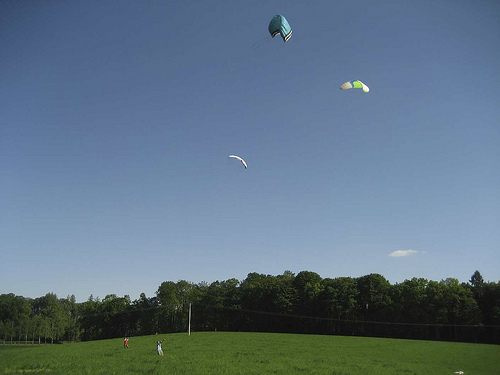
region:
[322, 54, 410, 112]
the kite is yellow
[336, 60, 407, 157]
the kite is yellow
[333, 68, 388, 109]
the kite is yellow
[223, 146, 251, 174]
A white kite im the air.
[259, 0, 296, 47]
A blue kite.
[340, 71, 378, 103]
A white and green kite.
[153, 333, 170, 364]
A boy holding a kite.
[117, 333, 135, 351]
A boy holding another kite.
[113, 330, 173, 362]
Two boys in a field.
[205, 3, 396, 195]
Kites flying through the air.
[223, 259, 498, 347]
A large group of trees.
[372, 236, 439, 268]
A cloud in the sky.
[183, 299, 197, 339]
A pole in the grass.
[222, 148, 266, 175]
White kite flying in the sky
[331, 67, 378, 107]
white and green kite flying in the sky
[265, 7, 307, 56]
Blue kite flying in the sky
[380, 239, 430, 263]
white cloud in the sky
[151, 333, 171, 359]
person flying a kite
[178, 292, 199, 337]
telephone pole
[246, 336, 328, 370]
section of the green pasture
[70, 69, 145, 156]
section of the blue sky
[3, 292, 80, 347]
section of trees in the background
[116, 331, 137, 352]
A kite flyer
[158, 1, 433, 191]
Kites in the sky.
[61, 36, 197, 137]
The ski is clear blue.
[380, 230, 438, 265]
A tiny cloud in the sky.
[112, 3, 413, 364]
The people in the field are flying kites.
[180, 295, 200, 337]
A power pole in the field.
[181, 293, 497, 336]
A power line strung to a pole.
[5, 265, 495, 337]
Green trees near a field.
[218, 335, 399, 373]
The grass is vibrant green.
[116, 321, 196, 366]
Two people in a field.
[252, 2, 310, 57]
A blue kite in the sky.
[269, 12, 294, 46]
blue black and white kite flown in air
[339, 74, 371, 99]
green and white kite flown in air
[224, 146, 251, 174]
white kite flown in air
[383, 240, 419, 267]
white cloud against blue sky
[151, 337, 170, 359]
person flying kites in air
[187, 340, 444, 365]
short green grass in field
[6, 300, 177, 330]
green trees in field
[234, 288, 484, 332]
green trees in field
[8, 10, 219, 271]
blue sky without clouds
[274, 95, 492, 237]
blue sky without clouds